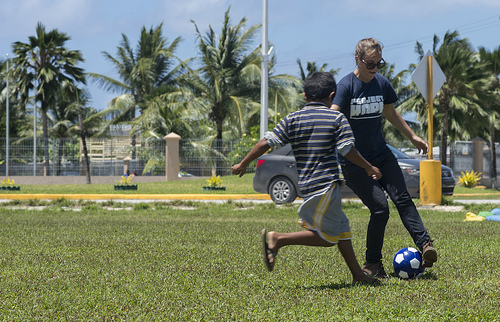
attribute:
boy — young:
[223, 66, 387, 311]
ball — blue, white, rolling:
[389, 238, 431, 282]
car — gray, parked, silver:
[245, 123, 460, 201]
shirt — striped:
[253, 103, 359, 200]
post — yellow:
[413, 41, 453, 207]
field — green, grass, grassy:
[4, 202, 500, 318]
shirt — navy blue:
[326, 66, 406, 173]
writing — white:
[348, 92, 384, 122]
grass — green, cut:
[3, 204, 500, 320]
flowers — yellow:
[454, 166, 484, 194]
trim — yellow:
[293, 189, 355, 242]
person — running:
[236, 70, 383, 297]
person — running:
[327, 25, 455, 283]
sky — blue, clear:
[0, 1, 494, 139]